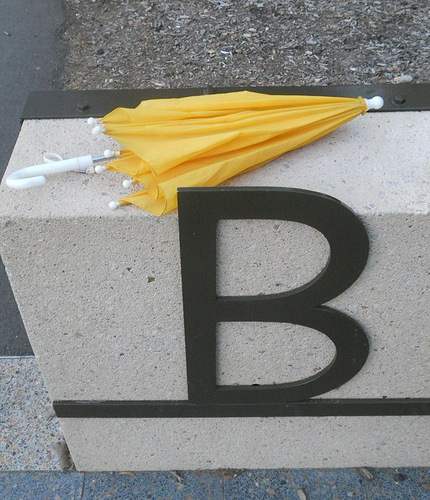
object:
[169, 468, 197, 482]
wood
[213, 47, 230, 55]
wood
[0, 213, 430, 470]
wall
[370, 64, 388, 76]
chip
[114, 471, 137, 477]
wood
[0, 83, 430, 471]
building